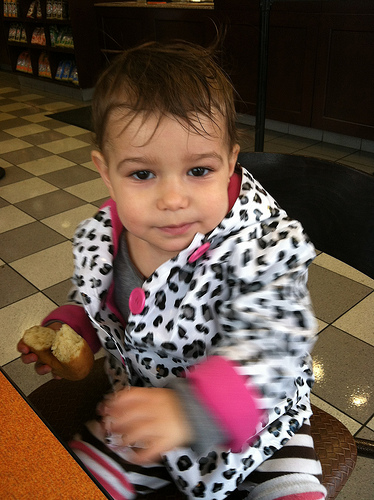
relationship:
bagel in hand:
[20, 322, 95, 381] [21, 346, 48, 377]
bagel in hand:
[20, 322, 95, 381] [12, 321, 67, 381]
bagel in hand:
[20, 322, 95, 381] [100, 361, 201, 471]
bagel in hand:
[20, 322, 95, 381] [14, 316, 72, 387]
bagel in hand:
[20, 322, 95, 381] [16, 316, 74, 376]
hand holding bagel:
[106, 386, 192, 464] [20, 322, 93, 381]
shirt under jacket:
[111, 236, 145, 324] [42, 166, 318, 498]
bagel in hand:
[20, 322, 95, 381] [8, 296, 181, 443]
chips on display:
[56, 65, 69, 81] [2, 2, 94, 93]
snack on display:
[39, 58, 45, 75] [2, 2, 94, 93]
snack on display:
[48, 30, 56, 43] [2, 2, 94, 93]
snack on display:
[30, 32, 38, 44] [2, 2, 94, 93]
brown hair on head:
[88, 24, 248, 151] [89, 45, 233, 233]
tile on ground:
[27, 159, 56, 180] [5, 114, 70, 265]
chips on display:
[51, 58, 68, 88] [2, 2, 94, 93]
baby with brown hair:
[17, 42, 329, 500] [88, 24, 248, 151]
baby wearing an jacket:
[17, 42, 329, 500] [49, 217, 314, 407]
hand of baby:
[97, 386, 194, 463] [17, 42, 329, 500]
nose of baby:
[163, 175, 190, 208] [17, 42, 329, 500]